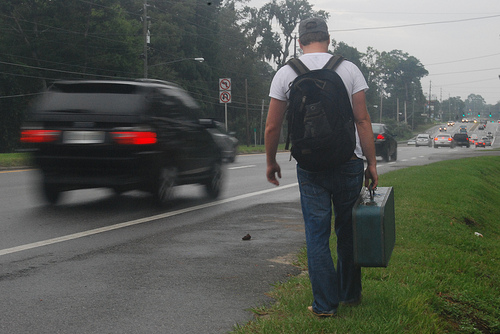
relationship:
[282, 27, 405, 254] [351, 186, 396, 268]
man holding case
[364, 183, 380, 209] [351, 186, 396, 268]
handle on case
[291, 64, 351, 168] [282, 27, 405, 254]
backpack on man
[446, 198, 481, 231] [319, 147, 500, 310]
hole in grass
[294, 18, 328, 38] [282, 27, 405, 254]
cap on man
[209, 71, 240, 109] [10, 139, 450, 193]
sign on highway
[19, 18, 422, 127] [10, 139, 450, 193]
trees by highway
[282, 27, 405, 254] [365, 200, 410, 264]
man carrying case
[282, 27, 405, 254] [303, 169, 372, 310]
man wearing jeans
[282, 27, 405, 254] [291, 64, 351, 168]
man wearing backpack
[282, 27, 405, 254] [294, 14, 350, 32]
man wearing cap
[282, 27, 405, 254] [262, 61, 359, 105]
man wearing shirt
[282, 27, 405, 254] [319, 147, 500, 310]
man on grass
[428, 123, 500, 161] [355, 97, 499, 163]
cars in background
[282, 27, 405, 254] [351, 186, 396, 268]
man carrying case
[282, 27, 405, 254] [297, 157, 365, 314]
man wearing jeans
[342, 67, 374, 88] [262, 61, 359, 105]
sleeves on shirt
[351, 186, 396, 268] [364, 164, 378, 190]
case in hand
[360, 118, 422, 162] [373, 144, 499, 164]
prius in road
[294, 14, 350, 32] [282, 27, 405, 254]
cap on man